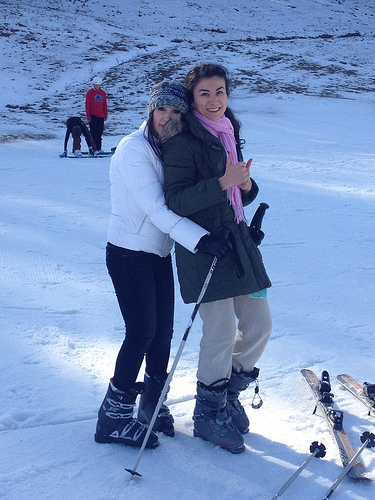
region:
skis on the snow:
[290, 338, 372, 450]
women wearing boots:
[101, 368, 266, 454]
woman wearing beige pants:
[193, 294, 268, 379]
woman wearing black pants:
[91, 248, 170, 379]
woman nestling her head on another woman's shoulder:
[107, 51, 249, 261]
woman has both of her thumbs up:
[213, 139, 267, 202]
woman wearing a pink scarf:
[183, 105, 243, 213]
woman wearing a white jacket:
[102, 122, 184, 252]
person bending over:
[52, 106, 95, 160]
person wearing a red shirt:
[77, 68, 117, 152]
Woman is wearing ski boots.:
[193, 364, 275, 459]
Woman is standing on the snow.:
[162, 63, 297, 455]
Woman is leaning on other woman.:
[96, 58, 291, 452]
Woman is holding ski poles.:
[123, 198, 283, 484]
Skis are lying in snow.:
[295, 361, 374, 494]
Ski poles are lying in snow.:
[265, 427, 373, 498]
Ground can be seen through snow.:
[2, 2, 373, 153]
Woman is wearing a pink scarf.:
[184, 102, 255, 227]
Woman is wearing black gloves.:
[196, 229, 234, 270]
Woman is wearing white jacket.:
[102, 112, 218, 264]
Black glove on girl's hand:
[187, 238, 222, 257]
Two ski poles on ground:
[263, 400, 361, 491]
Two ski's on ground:
[301, 362, 364, 434]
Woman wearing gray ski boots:
[197, 365, 269, 437]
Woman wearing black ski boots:
[109, 378, 192, 458]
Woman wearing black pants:
[76, 276, 177, 349]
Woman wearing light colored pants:
[192, 321, 279, 375]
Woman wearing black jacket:
[174, 261, 235, 280]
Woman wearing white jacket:
[112, 215, 172, 253]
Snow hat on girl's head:
[136, 72, 225, 155]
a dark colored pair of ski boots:
[95, 376, 184, 451]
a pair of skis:
[295, 363, 373, 486]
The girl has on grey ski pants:
[185, 288, 296, 382]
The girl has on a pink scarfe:
[193, 107, 261, 222]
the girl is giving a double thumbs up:
[223, 150, 264, 204]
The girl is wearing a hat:
[117, 73, 195, 148]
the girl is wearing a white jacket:
[107, 123, 215, 289]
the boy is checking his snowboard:
[57, 114, 114, 163]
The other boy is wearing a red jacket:
[85, 68, 113, 155]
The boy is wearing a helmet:
[87, 66, 106, 92]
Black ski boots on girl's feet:
[91, 371, 177, 461]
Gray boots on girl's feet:
[185, 364, 254, 439]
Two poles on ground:
[273, 418, 349, 497]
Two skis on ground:
[293, 345, 373, 409]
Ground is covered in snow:
[37, 342, 106, 463]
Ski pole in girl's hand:
[119, 272, 188, 408]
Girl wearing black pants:
[104, 278, 160, 342]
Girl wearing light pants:
[200, 308, 290, 373]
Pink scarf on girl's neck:
[203, 105, 282, 183]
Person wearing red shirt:
[64, 85, 132, 138]